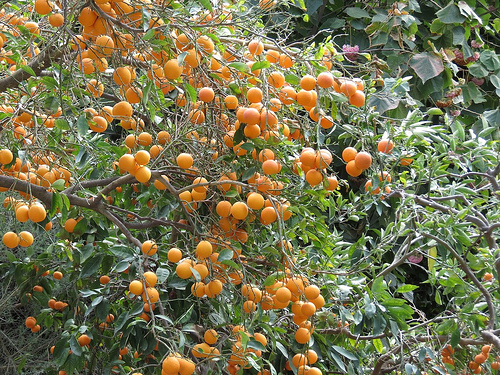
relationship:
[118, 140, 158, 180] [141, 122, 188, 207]
yellow fruits on vine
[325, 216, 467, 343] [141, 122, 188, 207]
leaves on vine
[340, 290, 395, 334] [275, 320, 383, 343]
leaves on vine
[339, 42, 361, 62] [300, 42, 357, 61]
purple leaf on vine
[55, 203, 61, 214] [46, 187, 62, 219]
brown spot on leaf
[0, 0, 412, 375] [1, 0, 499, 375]
yellow fruits on oranges/trees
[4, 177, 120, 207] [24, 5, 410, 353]
branche on tree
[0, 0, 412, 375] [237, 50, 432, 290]
yellow fruits on trees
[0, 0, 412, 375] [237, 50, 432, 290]
yellow fruits growing on trees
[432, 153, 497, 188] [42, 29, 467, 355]
branch on tree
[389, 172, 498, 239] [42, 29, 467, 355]
branch on tree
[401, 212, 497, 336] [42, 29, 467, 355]
branch on tree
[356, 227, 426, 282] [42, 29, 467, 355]
branch on tree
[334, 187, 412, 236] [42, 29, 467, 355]
branch on tree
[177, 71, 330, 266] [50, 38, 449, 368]
oranges on tree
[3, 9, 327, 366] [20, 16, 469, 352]
oranges on trees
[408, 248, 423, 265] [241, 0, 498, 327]
petal on tree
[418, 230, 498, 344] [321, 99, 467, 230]
brown stick with leaves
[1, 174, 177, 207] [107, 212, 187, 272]
brown stick with leaves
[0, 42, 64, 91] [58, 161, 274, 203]
brown stick with leaves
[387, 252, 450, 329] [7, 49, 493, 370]
hole in tree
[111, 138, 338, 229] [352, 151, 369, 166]
branch with fruit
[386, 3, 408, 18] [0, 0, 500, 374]
brown leaves in bush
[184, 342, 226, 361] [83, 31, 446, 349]
leaf on tree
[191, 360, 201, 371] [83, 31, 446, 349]
date on tree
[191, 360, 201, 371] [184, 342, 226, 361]
date on leaf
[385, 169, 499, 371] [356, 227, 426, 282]
green/leafy branches on branch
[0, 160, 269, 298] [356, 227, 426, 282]
green/leafy branches on branch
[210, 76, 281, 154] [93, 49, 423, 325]
orange on tree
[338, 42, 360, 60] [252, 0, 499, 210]
blossom on tree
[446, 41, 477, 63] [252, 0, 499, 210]
blossom on tree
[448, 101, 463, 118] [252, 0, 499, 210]
blossom on tree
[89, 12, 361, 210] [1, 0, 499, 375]
orange fruits on oranges/trees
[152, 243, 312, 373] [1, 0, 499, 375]
orange fruits on oranges/trees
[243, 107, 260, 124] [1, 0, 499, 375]
peach hangs from oranges/trees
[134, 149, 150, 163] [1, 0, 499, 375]
peach hangs from oranges/trees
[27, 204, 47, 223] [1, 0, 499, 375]
peach hangs from oranges/trees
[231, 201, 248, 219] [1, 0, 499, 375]
peach hangs from oranges/trees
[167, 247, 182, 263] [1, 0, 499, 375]
peach hangs from oranges/trees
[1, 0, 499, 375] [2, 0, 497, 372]
oranges/trees has fruit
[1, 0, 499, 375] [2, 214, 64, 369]
oranges/trees has branch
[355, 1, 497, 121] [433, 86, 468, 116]
plant has dead blossoms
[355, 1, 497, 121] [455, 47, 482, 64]
plant has dead blossoms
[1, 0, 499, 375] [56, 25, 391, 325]
oranges/trees has stuff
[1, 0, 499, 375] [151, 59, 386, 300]
oranges/trees has branches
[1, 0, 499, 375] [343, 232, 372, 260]
oranges/trees has leaf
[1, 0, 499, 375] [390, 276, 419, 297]
oranges/trees has leaf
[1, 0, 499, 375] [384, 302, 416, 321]
oranges/trees has leaf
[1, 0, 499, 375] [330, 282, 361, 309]
oranges/trees has leaf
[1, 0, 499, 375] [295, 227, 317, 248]
oranges/trees has leaf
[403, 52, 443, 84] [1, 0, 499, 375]
leaf on oranges/trees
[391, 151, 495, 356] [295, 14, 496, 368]
leaves are in background